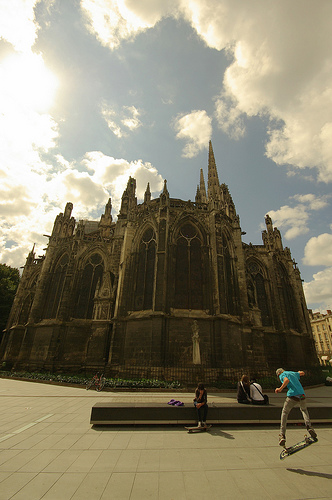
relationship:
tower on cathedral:
[14, 200, 79, 373] [0, 140, 319, 392]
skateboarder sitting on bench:
[190, 381, 214, 428] [86, 397, 329, 432]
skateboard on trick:
[276, 434, 318, 461] [276, 434, 319, 462]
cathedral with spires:
[0, 140, 325, 389] [203, 141, 221, 201]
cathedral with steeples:
[0, 140, 325, 389] [99, 197, 116, 226]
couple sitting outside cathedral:
[236, 374, 265, 405] [0, 140, 325, 389]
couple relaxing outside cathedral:
[236, 374, 265, 405] [0, 140, 325, 389]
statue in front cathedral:
[191, 327, 200, 364] [0, 140, 325, 389]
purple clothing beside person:
[167, 397, 185, 407] [192, 383, 208, 426]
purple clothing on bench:
[163, 396, 187, 407] [88, 399, 279, 427]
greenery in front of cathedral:
[15, 368, 152, 389] [0, 140, 325, 389]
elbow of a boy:
[284, 376, 290, 383] [274, 368, 318, 447]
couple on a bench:
[236, 374, 265, 405] [89, 399, 313, 425]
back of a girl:
[237, 382, 248, 400] [236, 374, 250, 404]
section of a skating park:
[151, 443, 171, 468] [5, 429, 278, 499]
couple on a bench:
[235, 374, 270, 404] [88, 399, 279, 427]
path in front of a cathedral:
[1, 365, 156, 389] [0, 140, 319, 392]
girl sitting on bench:
[192, 380, 214, 427] [84, 392, 330, 431]